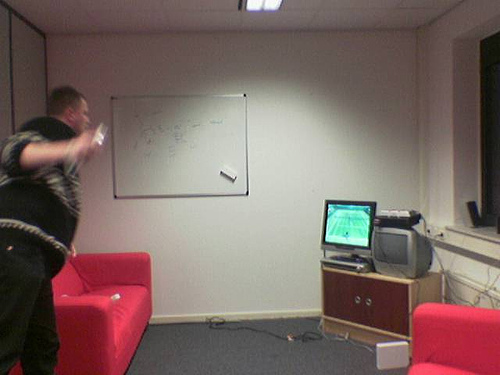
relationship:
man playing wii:
[3, 80, 105, 374] [374, 339, 409, 374]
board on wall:
[113, 91, 248, 195] [47, 29, 428, 314]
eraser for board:
[217, 164, 237, 182] [113, 91, 248, 195]